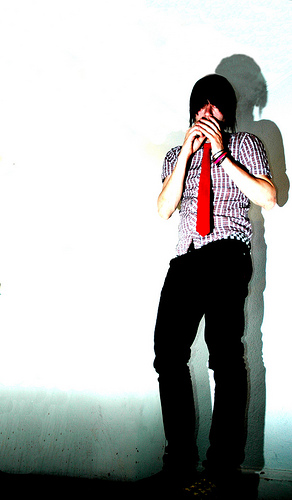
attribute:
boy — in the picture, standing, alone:
[138, 71, 277, 499]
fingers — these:
[188, 116, 221, 152]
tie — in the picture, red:
[196, 142, 213, 237]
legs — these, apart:
[133, 240, 254, 497]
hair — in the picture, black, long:
[189, 76, 238, 133]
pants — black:
[153, 239, 256, 466]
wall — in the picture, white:
[2, 1, 291, 498]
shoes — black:
[133, 473, 238, 498]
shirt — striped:
[162, 132, 273, 257]